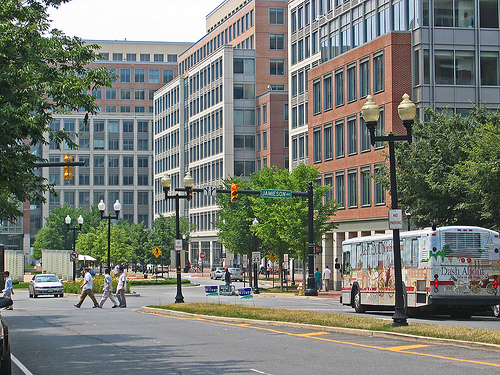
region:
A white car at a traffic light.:
[25, 274, 64, 297]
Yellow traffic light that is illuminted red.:
[229, 182, 238, 204]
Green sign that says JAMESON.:
[258, 187, 291, 200]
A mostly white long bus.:
[339, 224, 499, 319]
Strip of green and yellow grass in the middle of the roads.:
[151, 298, 498, 347]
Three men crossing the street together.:
[74, 267, 129, 309]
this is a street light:
[152, 169, 182, 204]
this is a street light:
[108, 192, 128, 219]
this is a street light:
[100, 192, 134, 229]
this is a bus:
[320, 202, 492, 347]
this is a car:
[28, 270, 60, 299]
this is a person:
[72, 263, 102, 325]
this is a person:
[109, 260, 133, 320]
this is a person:
[306, 248, 347, 311]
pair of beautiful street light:
[83, 189, 129, 216]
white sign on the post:
[382, 208, 410, 235]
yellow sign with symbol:
[146, 240, 171, 261]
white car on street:
[24, 268, 66, 295]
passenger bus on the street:
[326, 225, 493, 317]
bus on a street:
[335, 231, 376, 312]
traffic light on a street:
[216, 177, 246, 207]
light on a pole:
[390, 91, 430, 126]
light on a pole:
[346, 96, 386, 127]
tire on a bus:
[341, 277, 371, 320]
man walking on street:
[76, 263, 101, 310]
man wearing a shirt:
[75, 253, 100, 309]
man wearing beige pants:
[72, 258, 97, 318]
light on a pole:
[91, 192, 111, 222]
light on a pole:
[111, 199, 123, 220]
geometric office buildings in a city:
[9, 6, 491, 297]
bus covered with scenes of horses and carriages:
[339, 223, 498, 313]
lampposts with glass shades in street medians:
[61, 90, 421, 350]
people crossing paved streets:
[3, 264, 493, 371]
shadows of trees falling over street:
[3, 309, 255, 369]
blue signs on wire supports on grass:
[204, 282, 257, 314]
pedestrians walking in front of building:
[310, 232, 335, 294]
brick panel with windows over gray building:
[304, 3, 425, 230]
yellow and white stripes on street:
[8, 301, 495, 371]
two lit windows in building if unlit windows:
[45, 119, 150, 231]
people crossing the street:
[4, 266, 129, 308]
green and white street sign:
[261, 189, 296, 200]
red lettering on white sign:
[383, 211, 403, 228]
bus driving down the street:
[337, 222, 499, 317]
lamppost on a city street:
[151, 170, 203, 319]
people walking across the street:
[0, 267, 180, 319]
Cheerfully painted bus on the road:
[334, 224, 498, 316]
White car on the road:
[29, 267, 65, 299]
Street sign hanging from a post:
[262, 186, 298, 197]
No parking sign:
[173, 231, 184, 253]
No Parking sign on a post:
[387, 204, 405, 231]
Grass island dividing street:
[149, 288, 497, 350]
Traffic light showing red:
[227, 177, 242, 211]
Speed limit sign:
[248, 245, 265, 269]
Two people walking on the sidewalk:
[310, 262, 333, 291]